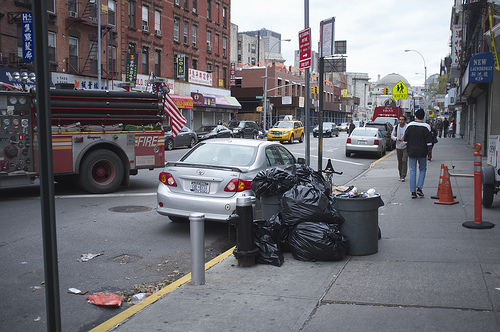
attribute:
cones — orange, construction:
[432, 167, 465, 216]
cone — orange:
[435, 166, 460, 204]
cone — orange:
[431, 162, 456, 199]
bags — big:
[251, 162, 348, 266]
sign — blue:
[468, 51, 494, 82]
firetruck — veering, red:
[0, 80, 165, 196]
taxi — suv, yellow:
[266, 114, 306, 143]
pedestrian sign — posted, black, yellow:
[391, 80, 408, 99]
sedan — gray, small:
[157, 139, 310, 226]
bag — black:
[288, 220, 348, 262]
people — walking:
[390, 107, 457, 200]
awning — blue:
[458, 53, 492, 102]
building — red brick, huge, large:
[0, 0, 243, 136]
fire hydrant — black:
[229, 193, 259, 267]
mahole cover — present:
[107, 204, 151, 213]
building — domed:
[370, 72, 411, 94]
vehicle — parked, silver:
[345, 125, 385, 157]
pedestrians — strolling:
[392, 107, 432, 198]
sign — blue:
[21, 13, 34, 63]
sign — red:
[298, 26, 311, 70]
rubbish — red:
[85, 291, 120, 308]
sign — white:
[187, 69, 214, 84]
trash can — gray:
[261, 193, 281, 220]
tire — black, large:
[77, 149, 124, 193]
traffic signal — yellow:
[311, 86, 320, 95]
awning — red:
[166, 94, 194, 110]